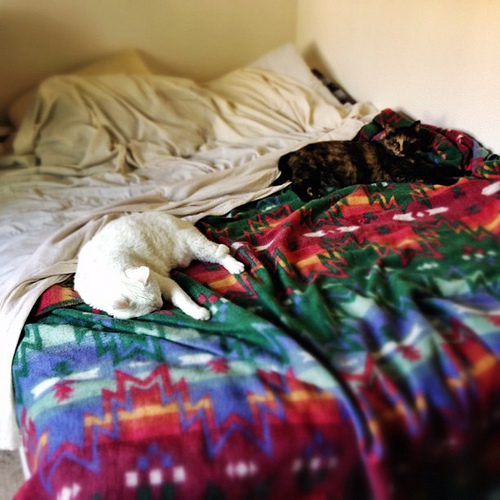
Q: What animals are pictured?
A: Cats.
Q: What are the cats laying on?
A: A bed.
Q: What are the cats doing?
A: Sleeping.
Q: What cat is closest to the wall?
A: The orange and black cat.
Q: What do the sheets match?
A: The wall.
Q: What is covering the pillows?
A: The sheet.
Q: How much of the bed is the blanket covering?
A: About half.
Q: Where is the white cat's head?
A: Laying on the blanket.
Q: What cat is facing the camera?
A: The black and orange cat.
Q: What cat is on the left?
A: The white cat.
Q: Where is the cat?
A: On the bed.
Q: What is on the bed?
A: A white cat.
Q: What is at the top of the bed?
A: A pillow.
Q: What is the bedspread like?
A: It is colorful.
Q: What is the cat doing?
A: It is sleeping on top of a bed.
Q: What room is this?
A: Bedroom.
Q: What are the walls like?
A: Painted white.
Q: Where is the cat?
A: In a bedroom.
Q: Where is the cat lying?
A: On the soft multi-colored blanket.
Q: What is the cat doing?
A: Relaxing on the bed.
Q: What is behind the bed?
A: A white wall.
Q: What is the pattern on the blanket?
A: Zigzagged lines.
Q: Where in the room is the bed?
A: In the corner of the room.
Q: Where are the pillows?
A: Against the wall.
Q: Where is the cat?
A: On a bed.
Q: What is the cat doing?
A: Sleeping.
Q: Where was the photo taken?
A: In a bedroom.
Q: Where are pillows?
A: On bed.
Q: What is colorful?
A: The blanket.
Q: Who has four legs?
A: The cat.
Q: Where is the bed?
A: In the corner of the room.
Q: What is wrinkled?
A: The bedsheets.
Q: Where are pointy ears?
A: On cat's head.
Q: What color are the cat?
A: White, black, and brown.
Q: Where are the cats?
A: On the bed.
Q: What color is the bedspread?
A: Red, blue, green, and orange.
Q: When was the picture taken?
A: Daytime.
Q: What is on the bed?
A: The cats.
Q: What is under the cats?
A: The bedspread.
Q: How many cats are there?
A: Two.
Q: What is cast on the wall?
A: Shadows.